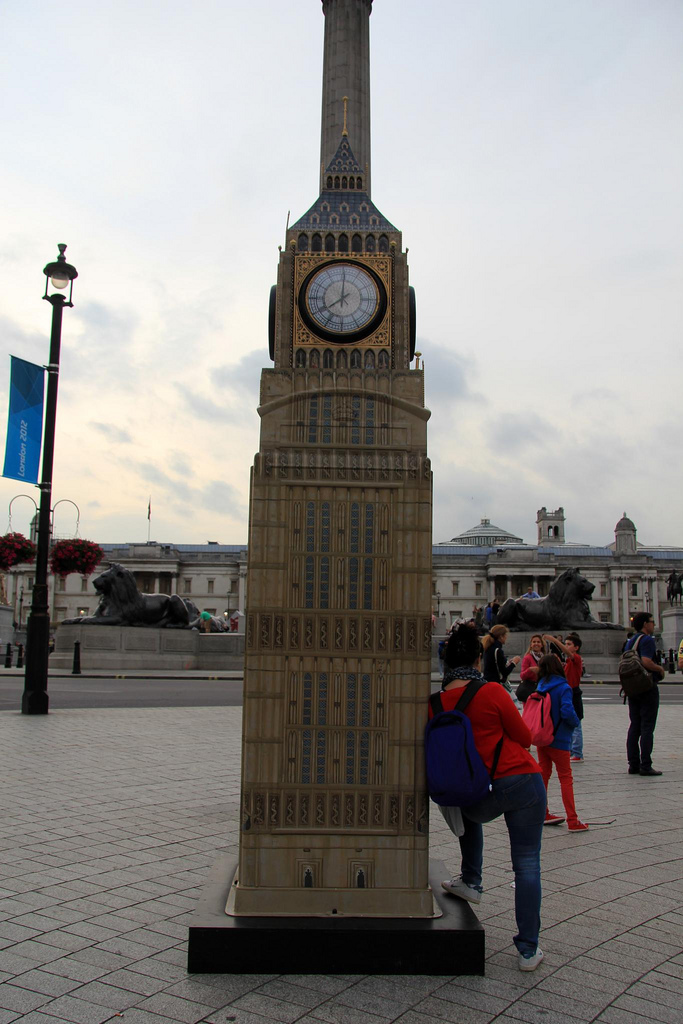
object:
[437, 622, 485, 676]
head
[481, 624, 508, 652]
head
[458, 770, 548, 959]
jeans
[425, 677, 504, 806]
bag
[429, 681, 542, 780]
sweater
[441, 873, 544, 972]
shoes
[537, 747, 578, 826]
pants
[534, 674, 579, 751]
jacket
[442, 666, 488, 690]
scarf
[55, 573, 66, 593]
window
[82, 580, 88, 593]
window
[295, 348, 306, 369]
window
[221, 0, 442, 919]
building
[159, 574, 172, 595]
window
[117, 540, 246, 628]
building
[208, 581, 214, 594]
window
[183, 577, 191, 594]
window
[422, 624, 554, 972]
person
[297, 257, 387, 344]
clock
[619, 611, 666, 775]
man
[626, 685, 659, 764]
pants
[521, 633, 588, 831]
girl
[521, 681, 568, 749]
backpack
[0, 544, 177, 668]
building